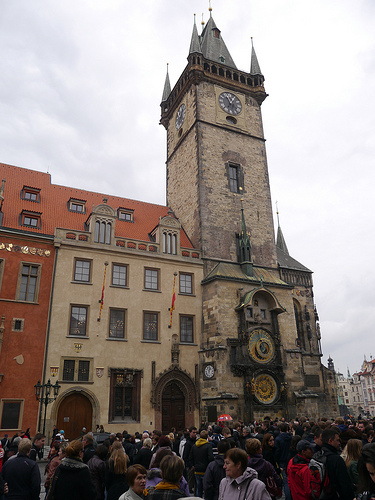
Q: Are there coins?
A: No, there are no coins.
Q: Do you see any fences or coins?
A: No, there are no coins or fences.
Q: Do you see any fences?
A: No, there are no fences.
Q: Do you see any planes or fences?
A: No, there are no fences or planes.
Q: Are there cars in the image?
A: No, there are no cars.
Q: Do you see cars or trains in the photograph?
A: No, there are no cars or trains.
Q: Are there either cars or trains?
A: No, there are no cars or trains.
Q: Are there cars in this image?
A: No, there are no cars.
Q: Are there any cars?
A: No, there are no cars.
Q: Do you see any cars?
A: No, there are no cars.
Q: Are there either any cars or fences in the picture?
A: No, there are no cars or fences.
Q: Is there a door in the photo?
A: Yes, there is a door.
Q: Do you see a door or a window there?
A: Yes, there is a door.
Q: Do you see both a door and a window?
A: Yes, there are both a door and a window.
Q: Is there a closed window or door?
A: Yes, there is a closed door.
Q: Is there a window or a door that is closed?
A: Yes, the door is closed.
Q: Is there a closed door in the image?
A: Yes, there is a closed door.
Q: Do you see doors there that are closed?
A: Yes, there is a door that is closed.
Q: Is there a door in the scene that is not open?
A: Yes, there is an closed door.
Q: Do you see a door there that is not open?
A: Yes, there is an closed door.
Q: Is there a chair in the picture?
A: No, there are no chairs.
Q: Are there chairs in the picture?
A: No, there are no chairs.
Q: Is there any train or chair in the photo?
A: No, there are no chairs or trains.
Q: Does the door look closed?
A: Yes, the door is closed.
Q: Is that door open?
A: No, the door is closed.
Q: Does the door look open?
A: No, the door is closed.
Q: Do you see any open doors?
A: No, there is a door but it is closed.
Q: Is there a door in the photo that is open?
A: No, there is a door but it is closed.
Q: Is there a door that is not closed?
A: No, there is a door but it is closed.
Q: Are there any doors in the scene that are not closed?
A: No, there is a door but it is closed.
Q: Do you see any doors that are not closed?
A: No, there is a door but it is closed.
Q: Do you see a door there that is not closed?
A: No, there is a door but it is closed.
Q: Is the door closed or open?
A: The door is closed.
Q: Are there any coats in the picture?
A: Yes, there is a coat.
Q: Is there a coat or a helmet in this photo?
A: Yes, there is a coat.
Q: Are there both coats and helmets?
A: No, there is a coat but no helmets.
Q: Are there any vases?
A: No, there are no vases.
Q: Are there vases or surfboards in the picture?
A: No, there are no vases or surfboards.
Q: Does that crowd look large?
A: Yes, the crowd is large.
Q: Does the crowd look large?
A: Yes, the crowd is large.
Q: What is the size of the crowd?
A: The crowd is large.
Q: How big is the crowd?
A: The crowd is large.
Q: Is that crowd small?
A: No, the crowd is large.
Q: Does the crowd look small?
A: No, the crowd is large.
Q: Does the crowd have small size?
A: No, the crowd is large.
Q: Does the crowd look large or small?
A: The crowd is large.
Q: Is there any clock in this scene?
A: Yes, there is a clock.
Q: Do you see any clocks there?
A: Yes, there is a clock.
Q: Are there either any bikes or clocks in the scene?
A: Yes, there is a clock.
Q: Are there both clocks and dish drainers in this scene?
A: No, there is a clock but no dish drainers.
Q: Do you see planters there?
A: No, there are no planters.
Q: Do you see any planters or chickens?
A: No, there are no planters or chickens.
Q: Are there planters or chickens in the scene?
A: No, there are no planters or chickens.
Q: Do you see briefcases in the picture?
A: No, there are no briefcases.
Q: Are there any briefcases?
A: No, there are no briefcases.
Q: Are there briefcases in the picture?
A: No, there are no briefcases.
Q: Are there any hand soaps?
A: No, there are no hand soaps.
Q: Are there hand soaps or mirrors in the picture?
A: No, there are no hand soaps or mirrors.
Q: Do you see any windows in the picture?
A: Yes, there is a window.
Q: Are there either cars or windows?
A: Yes, there is a window.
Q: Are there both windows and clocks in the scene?
A: Yes, there are both a window and a clock.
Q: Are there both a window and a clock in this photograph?
A: Yes, there are both a window and a clock.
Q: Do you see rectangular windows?
A: Yes, there is a rectangular window.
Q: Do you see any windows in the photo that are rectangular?
A: Yes, there is a window that is rectangular.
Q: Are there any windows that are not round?
A: Yes, there is a rectangular window.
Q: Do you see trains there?
A: No, there are no trains.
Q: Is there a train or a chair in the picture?
A: No, there are no trains or chairs.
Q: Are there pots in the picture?
A: No, there are no pots.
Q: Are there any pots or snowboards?
A: No, there are no pots or snowboards.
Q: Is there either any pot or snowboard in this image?
A: No, there are no pots or snowboards.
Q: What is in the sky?
A: The clouds are in the sky.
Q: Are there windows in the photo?
A: Yes, there is a window.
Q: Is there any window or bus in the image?
A: Yes, there is a window.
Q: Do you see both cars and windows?
A: No, there is a window but no cars.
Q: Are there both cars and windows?
A: No, there is a window but no cars.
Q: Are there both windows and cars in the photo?
A: No, there is a window but no cars.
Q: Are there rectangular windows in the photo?
A: Yes, there is a rectangular window.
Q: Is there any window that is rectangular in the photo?
A: Yes, there is a rectangular window.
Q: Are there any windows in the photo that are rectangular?
A: Yes, there is a window that is rectangular.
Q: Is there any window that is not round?
A: Yes, there is a rectangular window.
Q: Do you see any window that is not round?
A: Yes, there is a rectangular window.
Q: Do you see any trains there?
A: No, there are no trains.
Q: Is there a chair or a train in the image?
A: No, there are no trains or chairs.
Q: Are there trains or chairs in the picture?
A: No, there are no trains or chairs.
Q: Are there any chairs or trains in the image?
A: No, there are no trains or chairs.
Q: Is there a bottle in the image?
A: No, there are no bottles.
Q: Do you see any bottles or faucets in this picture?
A: No, there are no bottles or faucets.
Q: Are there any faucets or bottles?
A: No, there are no bottles or faucets.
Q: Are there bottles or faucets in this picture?
A: No, there are no bottles or faucets.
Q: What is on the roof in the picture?
A: The tiles are on the roof.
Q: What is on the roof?
A: The tiles are on the roof.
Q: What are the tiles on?
A: The tiles are on the roof.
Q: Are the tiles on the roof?
A: Yes, the tiles are on the roof.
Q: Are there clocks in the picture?
A: Yes, there is a clock.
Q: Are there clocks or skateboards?
A: Yes, there is a clock.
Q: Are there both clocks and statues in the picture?
A: No, there is a clock but no statues.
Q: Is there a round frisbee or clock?
A: Yes, there is a round clock.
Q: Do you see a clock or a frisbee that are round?
A: Yes, the clock is round.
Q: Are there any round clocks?
A: Yes, there is a round clock.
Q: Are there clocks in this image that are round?
A: Yes, there is a clock that is round.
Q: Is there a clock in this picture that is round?
A: Yes, there is a clock that is round.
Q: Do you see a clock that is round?
A: Yes, there is a clock that is round.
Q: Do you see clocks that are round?
A: Yes, there is a clock that is round.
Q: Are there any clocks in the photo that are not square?
A: Yes, there is a round clock.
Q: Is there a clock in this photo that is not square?
A: Yes, there is a round clock.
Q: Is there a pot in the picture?
A: No, there are no pots.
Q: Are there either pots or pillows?
A: No, there are no pots or pillows.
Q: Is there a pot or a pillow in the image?
A: No, there are no pots or pillows.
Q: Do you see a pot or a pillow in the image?
A: No, there are no pots or pillows.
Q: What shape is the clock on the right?
A: The clock is round.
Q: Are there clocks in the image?
A: Yes, there is a clock.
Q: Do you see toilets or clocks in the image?
A: Yes, there is a clock.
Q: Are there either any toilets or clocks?
A: Yes, there is a clock.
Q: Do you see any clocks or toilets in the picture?
A: Yes, there is a clock.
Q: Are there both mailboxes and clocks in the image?
A: No, there is a clock but no mailboxes.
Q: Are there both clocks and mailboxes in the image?
A: No, there is a clock but no mailboxes.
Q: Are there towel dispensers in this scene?
A: No, there are no towel dispensers.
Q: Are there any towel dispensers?
A: No, there are no towel dispensers.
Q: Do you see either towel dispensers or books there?
A: No, there are no towel dispensers or books.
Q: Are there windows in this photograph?
A: Yes, there are windows.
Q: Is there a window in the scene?
A: Yes, there are windows.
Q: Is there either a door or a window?
A: Yes, there are windows.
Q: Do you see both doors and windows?
A: Yes, there are both windows and a door.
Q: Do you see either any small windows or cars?
A: Yes, there are small windows.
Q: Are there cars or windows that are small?
A: Yes, the windows are small.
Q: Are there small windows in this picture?
A: Yes, there are small windows.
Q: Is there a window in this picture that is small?
A: Yes, there are windows that are small.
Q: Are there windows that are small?
A: Yes, there are windows that are small.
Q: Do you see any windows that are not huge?
A: Yes, there are small windows.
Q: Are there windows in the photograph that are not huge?
A: Yes, there are small windows.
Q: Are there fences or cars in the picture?
A: No, there are no cars or fences.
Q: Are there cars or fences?
A: No, there are no cars or fences.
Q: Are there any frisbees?
A: No, there are no frisbees.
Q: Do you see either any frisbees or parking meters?
A: No, there are no frisbees or parking meters.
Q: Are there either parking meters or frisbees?
A: No, there are no frisbees or parking meters.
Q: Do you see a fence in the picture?
A: No, there are no fences.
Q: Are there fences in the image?
A: No, there are no fences.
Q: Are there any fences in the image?
A: No, there are no fences.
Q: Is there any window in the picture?
A: Yes, there are windows.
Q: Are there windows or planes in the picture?
A: Yes, there are windows.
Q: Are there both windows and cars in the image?
A: No, there are windows but no cars.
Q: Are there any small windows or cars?
A: Yes, there are small windows.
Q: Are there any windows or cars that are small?
A: Yes, the windows are small.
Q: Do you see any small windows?
A: Yes, there are small windows.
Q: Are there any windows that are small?
A: Yes, there are windows that are small.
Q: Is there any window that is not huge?
A: Yes, there are small windows.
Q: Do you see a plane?
A: No, there are no airplanes.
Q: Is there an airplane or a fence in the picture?
A: No, there are no airplanes or fences.